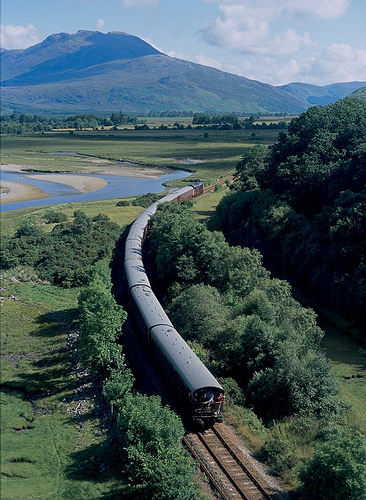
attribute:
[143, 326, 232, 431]
cars — gray, train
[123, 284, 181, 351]
cars — gray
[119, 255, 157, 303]
cars — gray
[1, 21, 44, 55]
clouds — white, large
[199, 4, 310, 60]
clouds — white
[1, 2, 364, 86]
sky — blue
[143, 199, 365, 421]
trees — green, tall, separating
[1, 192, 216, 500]
grass — green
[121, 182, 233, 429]
train — metal, long, silver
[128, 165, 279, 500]
tracks — brown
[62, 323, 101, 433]
gravel — grey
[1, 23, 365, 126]
mountainside — large, grassy, distance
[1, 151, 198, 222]
pond — small, for irrigation